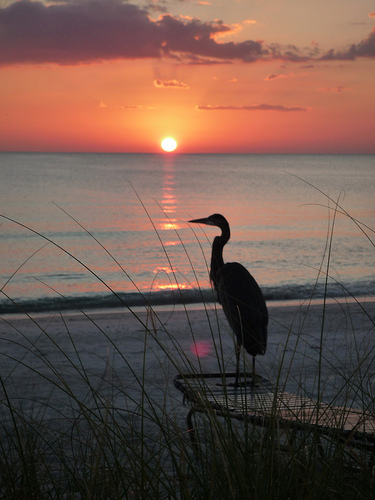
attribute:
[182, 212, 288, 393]
bird — standing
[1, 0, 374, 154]
sky — purple, cloudy, setting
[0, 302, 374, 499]
beach — sandy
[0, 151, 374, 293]
water — blue, reflective